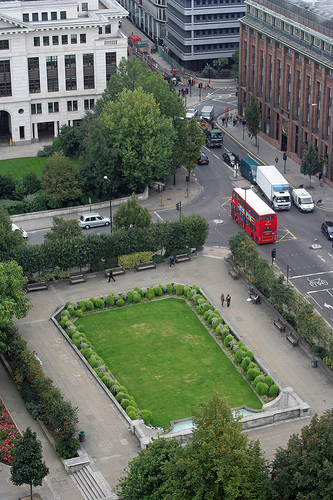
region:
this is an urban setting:
[21, 93, 318, 390]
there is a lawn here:
[89, 306, 249, 403]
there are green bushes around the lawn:
[60, 279, 229, 367]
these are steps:
[62, 460, 128, 498]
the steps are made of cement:
[71, 463, 110, 495]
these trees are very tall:
[148, 416, 316, 498]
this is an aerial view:
[1, 176, 311, 437]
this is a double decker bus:
[220, 172, 292, 258]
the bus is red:
[216, 173, 298, 265]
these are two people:
[203, 282, 248, 319]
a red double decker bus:
[230, 185, 277, 243]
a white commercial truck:
[254, 164, 290, 211]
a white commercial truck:
[290, 188, 313, 212]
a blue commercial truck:
[239, 157, 257, 182]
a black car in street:
[221, 151, 239, 168]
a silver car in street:
[76, 210, 110, 227]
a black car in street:
[196, 149, 207, 163]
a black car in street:
[321, 220, 332, 243]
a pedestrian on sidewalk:
[107, 269, 115, 283]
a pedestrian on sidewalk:
[219, 291, 223, 306]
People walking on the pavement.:
[216, 283, 240, 311]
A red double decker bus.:
[222, 175, 283, 256]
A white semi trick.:
[253, 155, 294, 213]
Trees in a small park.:
[10, 421, 62, 495]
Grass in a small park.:
[125, 328, 179, 391]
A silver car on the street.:
[73, 210, 113, 225]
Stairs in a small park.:
[68, 469, 110, 498]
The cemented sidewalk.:
[106, 183, 201, 204]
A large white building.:
[0, 2, 137, 152]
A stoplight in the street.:
[169, 194, 188, 222]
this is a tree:
[122, 192, 148, 234]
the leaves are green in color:
[196, 451, 240, 486]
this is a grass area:
[140, 336, 206, 389]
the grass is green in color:
[146, 317, 168, 348]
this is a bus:
[236, 188, 272, 225]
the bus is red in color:
[257, 220, 266, 236]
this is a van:
[290, 187, 315, 205]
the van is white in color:
[298, 187, 304, 192]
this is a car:
[80, 212, 108, 226]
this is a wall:
[18, 50, 79, 98]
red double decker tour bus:
[226, 180, 285, 252]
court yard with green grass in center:
[36, 271, 314, 455]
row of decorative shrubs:
[170, 275, 292, 402]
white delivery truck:
[248, 156, 293, 215]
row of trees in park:
[0, 342, 108, 480]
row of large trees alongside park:
[97, 399, 327, 497]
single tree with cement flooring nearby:
[8, 420, 49, 497]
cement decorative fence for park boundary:
[101, 388, 314, 459]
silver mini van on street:
[76, 210, 120, 235]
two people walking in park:
[215, 280, 237, 316]